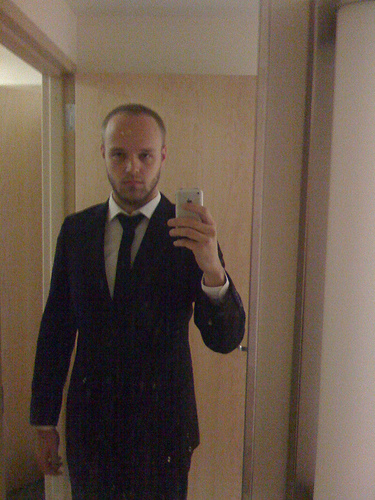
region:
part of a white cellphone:
[174, 185, 205, 218]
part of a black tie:
[110, 209, 143, 303]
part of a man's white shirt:
[100, 191, 162, 294]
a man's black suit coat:
[26, 196, 244, 441]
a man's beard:
[103, 164, 162, 206]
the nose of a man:
[122, 151, 142, 175]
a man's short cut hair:
[101, 101, 170, 141]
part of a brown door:
[79, 72, 260, 498]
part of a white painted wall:
[290, 3, 371, 498]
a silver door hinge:
[63, 104, 79, 134]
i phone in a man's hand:
[173, 175, 203, 239]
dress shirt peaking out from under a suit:
[28, 411, 55, 434]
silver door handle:
[234, 340, 251, 360]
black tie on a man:
[105, 207, 144, 309]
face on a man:
[104, 122, 156, 200]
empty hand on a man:
[23, 419, 63, 479]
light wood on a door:
[208, 372, 226, 415]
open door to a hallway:
[277, 359, 308, 444]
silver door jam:
[60, 98, 78, 136]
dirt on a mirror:
[94, 308, 202, 494]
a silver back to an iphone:
[173, 182, 203, 222]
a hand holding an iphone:
[171, 185, 253, 352]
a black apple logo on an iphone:
[185, 197, 194, 204]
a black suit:
[26, 195, 247, 498]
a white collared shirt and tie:
[104, 190, 159, 301]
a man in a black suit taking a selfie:
[23, 100, 250, 498]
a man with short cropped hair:
[99, 96, 168, 205]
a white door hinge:
[61, 103, 77, 130]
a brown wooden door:
[68, 76, 260, 498]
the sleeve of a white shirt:
[199, 274, 231, 301]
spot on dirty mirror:
[165, 453, 174, 463]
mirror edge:
[193, 39, 263, 191]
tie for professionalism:
[110, 211, 143, 290]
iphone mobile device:
[173, 187, 204, 235]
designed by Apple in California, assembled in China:
[174, 188, 204, 231]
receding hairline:
[99, 108, 163, 147]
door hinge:
[57, 74, 81, 140]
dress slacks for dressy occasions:
[65, 435, 195, 498]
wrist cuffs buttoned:
[197, 275, 232, 294]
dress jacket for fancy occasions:
[91, 270, 172, 406]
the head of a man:
[82, 108, 203, 189]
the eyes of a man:
[103, 142, 168, 169]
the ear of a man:
[91, 127, 129, 159]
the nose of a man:
[119, 159, 146, 182]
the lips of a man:
[113, 172, 160, 191]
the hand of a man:
[150, 197, 251, 262]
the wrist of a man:
[196, 248, 245, 299]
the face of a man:
[80, 115, 214, 230]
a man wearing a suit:
[39, 103, 319, 463]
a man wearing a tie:
[87, 148, 227, 310]